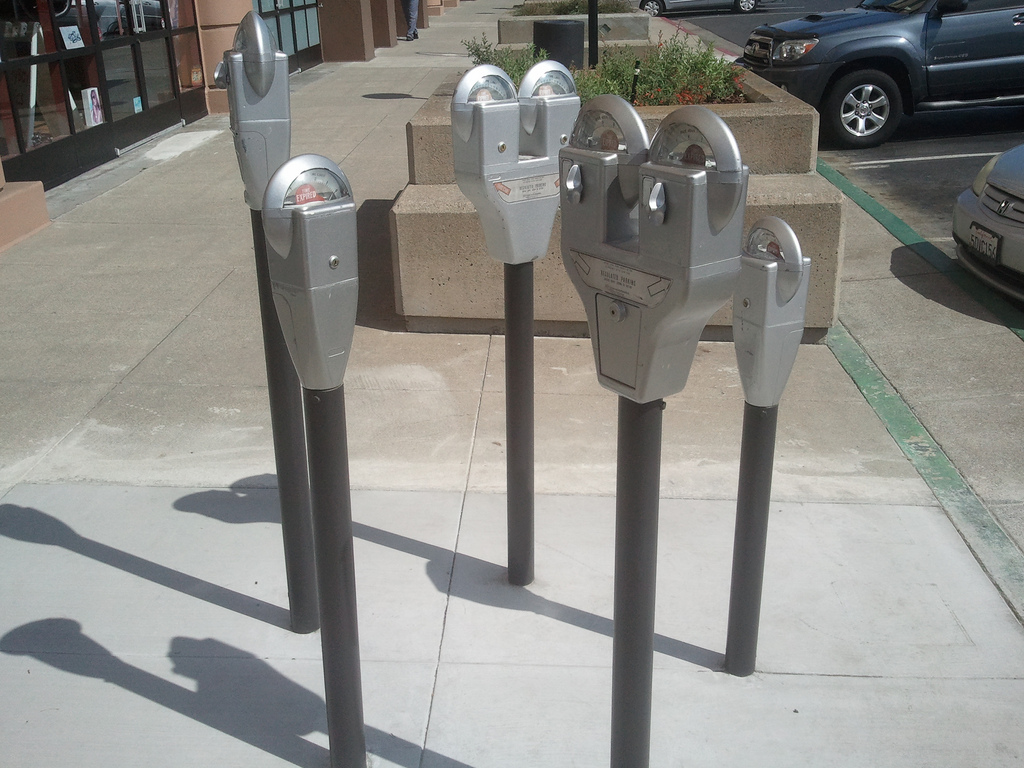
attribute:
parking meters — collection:
[211, 11, 825, 761]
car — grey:
[932, 141, 1023, 284]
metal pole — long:
[714, 404, 782, 681]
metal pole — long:
[493, 262, 554, 582]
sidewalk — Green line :
[8, 253, 223, 765]